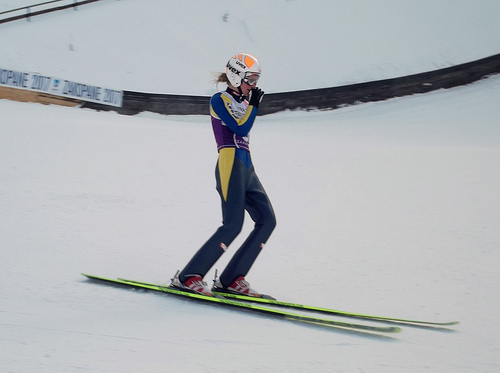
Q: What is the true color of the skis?
A: Green.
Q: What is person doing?
A: Skiing.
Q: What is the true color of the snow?
A: White.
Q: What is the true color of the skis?
A: Black and green.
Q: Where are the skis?
A: On the woman's feet.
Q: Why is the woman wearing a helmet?
A: Safety.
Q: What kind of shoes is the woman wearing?
A: Ski shoes.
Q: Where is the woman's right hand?
A: Next to mouth.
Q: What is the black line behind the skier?
A: Divider.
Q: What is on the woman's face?
A: Ski goggles.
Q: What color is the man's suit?
A: Blue and yellow.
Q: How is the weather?
A: Clear.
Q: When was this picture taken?
A: Daytime.